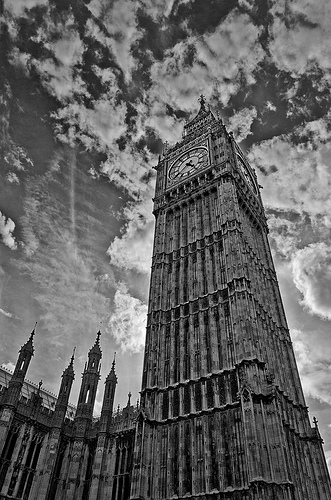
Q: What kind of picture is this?
A: A black and white photo.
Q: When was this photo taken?
A: During the daytime.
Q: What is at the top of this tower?
A: A clock.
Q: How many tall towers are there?
A: One.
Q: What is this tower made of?
A: Stone.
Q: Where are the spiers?
A: On the shorter building.